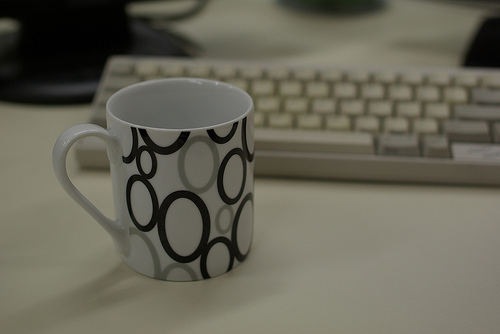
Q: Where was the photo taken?
A: In a room.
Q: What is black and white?
A: The cup.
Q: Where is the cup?
A: On the table.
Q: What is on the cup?
A: A design.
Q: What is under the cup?
A: A white table.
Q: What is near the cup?
A: Keyboard.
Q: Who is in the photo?
A: No people.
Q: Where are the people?
A: None in photo.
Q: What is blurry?
A: Nothing.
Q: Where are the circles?
A: On the cup.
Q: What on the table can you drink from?
A: The cup.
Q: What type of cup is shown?
A: A mug.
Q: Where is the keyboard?
A: Behind the mug.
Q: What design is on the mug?
A: Circles.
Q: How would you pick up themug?
A: The handle.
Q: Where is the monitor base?
A: Behind the keyboard/.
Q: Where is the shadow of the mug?
A: To the left of the mug.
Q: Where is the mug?
A: On the desk.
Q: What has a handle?
A: The mug.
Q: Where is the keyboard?
A: On the desk.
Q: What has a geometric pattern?
A: The mug.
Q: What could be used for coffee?
A: The mug.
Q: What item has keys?
A: The keyboard.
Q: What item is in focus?
A: The mug.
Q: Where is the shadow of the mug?
A: On the desk.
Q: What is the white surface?
A: A desk.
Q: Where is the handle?
A: On the mug.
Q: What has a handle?
A: The cup.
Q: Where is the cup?
A: On the table.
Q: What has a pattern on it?
A: The cup.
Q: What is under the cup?
A: The table.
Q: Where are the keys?
A: On the keyboard.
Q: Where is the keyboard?
A: Next to the cup.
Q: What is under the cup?
A: The table.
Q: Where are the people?
A: None in photo.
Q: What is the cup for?
A: Drinking.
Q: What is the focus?
A: Coffee mug at office.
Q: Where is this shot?
A: Desk.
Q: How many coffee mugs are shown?
A: 1.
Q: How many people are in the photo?
A: 0.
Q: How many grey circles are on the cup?
A: 4.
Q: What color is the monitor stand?
A: Black.